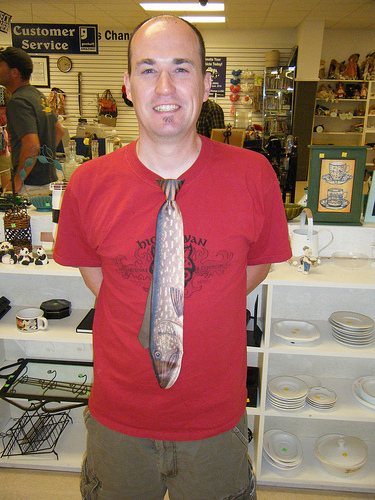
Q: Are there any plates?
A: Yes, there is a plate.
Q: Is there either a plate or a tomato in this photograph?
A: Yes, there is a plate.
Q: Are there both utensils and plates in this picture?
A: No, there is a plate but no utensils.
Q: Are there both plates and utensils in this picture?
A: No, there is a plate but no utensils.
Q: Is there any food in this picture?
A: No, there is no food.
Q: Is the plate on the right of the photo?
A: Yes, the plate is on the right of the image.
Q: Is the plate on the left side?
A: No, the plate is on the right of the image.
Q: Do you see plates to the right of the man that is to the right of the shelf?
A: Yes, there is a plate to the right of the man.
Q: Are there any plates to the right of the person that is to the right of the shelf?
A: Yes, there is a plate to the right of the man.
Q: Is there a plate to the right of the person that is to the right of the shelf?
A: Yes, there is a plate to the right of the man.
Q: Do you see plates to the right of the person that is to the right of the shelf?
A: Yes, there is a plate to the right of the man.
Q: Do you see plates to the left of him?
A: No, the plate is to the right of the man.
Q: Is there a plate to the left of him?
A: No, the plate is to the right of the man.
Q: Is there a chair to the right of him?
A: No, there is a plate to the right of the man.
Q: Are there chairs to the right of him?
A: No, there is a plate to the right of the man.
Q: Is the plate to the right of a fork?
A: No, the plate is to the right of a man.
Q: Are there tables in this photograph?
A: No, there are no tables.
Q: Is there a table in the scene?
A: No, there are no tables.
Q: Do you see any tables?
A: No, there are no tables.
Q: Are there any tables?
A: No, there are no tables.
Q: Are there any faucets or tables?
A: No, there are no tables or faucets.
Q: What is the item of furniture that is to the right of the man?
A: The piece of furniture is a shelf.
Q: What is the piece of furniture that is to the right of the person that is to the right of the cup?
A: The piece of furniture is a shelf.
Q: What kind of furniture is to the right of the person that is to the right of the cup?
A: The piece of furniture is a shelf.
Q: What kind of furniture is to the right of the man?
A: The piece of furniture is a shelf.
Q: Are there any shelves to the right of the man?
A: Yes, there is a shelf to the right of the man.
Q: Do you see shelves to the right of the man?
A: Yes, there is a shelf to the right of the man.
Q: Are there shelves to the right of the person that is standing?
A: Yes, there is a shelf to the right of the man.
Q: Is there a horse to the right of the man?
A: No, there is a shelf to the right of the man.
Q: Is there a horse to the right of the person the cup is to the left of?
A: No, there is a shelf to the right of the man.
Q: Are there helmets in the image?
A: No, there are no helmets.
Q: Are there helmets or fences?
A: No, there are no helmets or fences.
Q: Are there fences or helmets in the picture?
A: No, there are no helmets or fences.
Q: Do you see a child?
A: No, there are no children.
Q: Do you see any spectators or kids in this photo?
A: No, there are no kids or spectators.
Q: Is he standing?
A: Yes, the man is standing.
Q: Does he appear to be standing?
A: Yes, the man is standing.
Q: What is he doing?
A: The man is standing.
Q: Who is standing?
A: The man is standing.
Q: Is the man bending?
A: No, the man is standing.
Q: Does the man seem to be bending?
A: No, the man is standing.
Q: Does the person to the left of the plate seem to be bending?
A: No, the man is standing.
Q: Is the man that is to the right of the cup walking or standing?
A: The man is standing.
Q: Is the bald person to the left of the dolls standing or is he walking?
A: The man is standing.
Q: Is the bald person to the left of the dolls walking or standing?
A: The man is standing.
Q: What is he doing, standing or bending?
A: The man is standing.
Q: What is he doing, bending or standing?
A: The man is standing.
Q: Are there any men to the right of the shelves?
A: No, the man is to the left of the shelves.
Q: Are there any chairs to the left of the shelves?
A: No, there is a man to the left of the shelves.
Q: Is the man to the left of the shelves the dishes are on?
A: Yes, the man is to the left of the shelves.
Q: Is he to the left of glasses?
A: No, the man is to the left of the shelves.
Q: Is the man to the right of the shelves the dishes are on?
A: No, the man is to the left of the shelves.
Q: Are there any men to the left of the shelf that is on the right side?
A: Yes, there is a man to the left of the shelf.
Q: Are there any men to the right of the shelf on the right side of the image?
A: No, the man is to the left of the shelf.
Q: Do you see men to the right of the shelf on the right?
A: No, the man is to the left of the shelf.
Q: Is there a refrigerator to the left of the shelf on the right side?
A: No, there is a man to the left of the shelf.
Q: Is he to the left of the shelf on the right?
A: Yes, the man is to the left of the shelf.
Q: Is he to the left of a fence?
A: No, the man is to the left of the shelf.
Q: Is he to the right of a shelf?
A: No, the man is to the left of a shelf.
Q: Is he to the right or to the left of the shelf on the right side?
A: The man is to the left of the shelf.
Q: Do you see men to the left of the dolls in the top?
A: Yes, there is a man to the left of the dolls.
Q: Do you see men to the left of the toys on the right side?
A: Yes, there is a man to the left of the dolls.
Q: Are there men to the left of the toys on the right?
A: Yes, there is a man to the left of the dolls.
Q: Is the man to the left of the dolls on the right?
A: Yes, the man is to the left of the dolls.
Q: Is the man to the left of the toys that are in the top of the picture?
A: Yes, the man is to the left of the dolls.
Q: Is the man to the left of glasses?
A: No, the man is to the left of the dolls.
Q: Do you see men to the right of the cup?
A: Yes, there is a man to the right of the cup.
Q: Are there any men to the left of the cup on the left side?
A: No, the man is to the right of the cup.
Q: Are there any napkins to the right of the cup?
A: No, there is a man to the right of the cup.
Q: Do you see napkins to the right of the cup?
A: No, there is a man to the right of the cup.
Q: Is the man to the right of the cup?
A: Yes, the man is to the right of the cup.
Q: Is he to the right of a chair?
A: No, the man is to the right of the cup.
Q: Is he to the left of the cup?
A: No, the man is to the right of the cup.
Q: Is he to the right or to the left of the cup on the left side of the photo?
A: The man is to the right of the cup.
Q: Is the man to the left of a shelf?
A: No, the man is to the right of a shelf.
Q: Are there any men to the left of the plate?
A: Yes, there is a man to the left of the plate.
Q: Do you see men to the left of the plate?
A: Yes, there is a man to the left of the plate.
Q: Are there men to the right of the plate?
A: No, the man is to the left of the plate.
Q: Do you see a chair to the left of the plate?
A: No, there is a man to the left of the plate.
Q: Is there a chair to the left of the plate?
A: No, there is a man to the left of the plate.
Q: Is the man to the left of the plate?
A: Yes, the man is to the left of the plate.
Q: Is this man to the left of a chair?
A: No, the man is to the left of the plate.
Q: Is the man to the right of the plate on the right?
A: No, the man is to the left of the plate.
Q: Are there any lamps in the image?
A: No, there are no lamps.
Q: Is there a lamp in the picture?
A: No, there are no lamps.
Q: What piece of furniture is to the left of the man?
A: The piece of furniture is a shelf.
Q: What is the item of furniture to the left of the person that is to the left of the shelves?
A: The piece of furniture is a shelf.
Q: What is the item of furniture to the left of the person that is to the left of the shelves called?
A: The piece of furniture is a shelf.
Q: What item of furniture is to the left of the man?
A: The piece of furniture is a shelf.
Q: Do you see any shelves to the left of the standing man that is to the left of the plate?
A: Yes, there is a shelf to the left of the man.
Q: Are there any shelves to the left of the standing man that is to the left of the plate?
A: Yes, there is a shelf to the left of the man.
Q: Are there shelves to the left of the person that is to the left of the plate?
A: Yes, there is a shelf to the left of the man.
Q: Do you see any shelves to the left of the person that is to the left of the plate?
A: Yes, there is a shelf to the left of the man.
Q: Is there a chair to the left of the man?
A: No, there is a shelf to the left of the man.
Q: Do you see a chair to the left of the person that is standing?
A: No, there is a shelf to the left of the man.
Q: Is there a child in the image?
A: No, there are no children.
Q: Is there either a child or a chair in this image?
A: No, there are no children or chairs.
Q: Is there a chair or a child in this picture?
A: No, there are no children or chairs.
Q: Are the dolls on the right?
A: Yes, the dolls are on the right of the image.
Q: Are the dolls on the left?
A: No, the dolls are on the right of the image.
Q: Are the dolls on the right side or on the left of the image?
A: The dolls are on the right of the image.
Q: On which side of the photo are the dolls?
A: The dolls are on the right of the image.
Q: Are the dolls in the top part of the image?
A: Yes, the dolls are in the top of the image.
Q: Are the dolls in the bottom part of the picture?
A: No, the dolls are in the top of the image.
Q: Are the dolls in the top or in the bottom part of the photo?
A: The dolls are in the top of the image.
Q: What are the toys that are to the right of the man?
A: The toys are dolls.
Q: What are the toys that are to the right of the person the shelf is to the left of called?
A: The toys are dolls.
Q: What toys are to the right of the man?
A: The toys are dolls.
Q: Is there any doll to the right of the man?
A: Yes, there are dolls to the right of the man.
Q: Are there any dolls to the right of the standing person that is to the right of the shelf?
A: Yes, there are dolls to the right of the man.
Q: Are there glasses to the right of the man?
A: No, there are dolls to the right of the man.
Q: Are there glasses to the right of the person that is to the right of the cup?
A: No, there are dolls to the right of the man.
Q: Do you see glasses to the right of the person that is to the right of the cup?
A: No, there are dolls to the right of the man.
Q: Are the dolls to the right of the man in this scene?
A: Yes, the dolls are to the right of the man.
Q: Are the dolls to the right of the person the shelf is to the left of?
A: Yes, the dolls are to the right of the man.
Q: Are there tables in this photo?
A: No, there are no tables.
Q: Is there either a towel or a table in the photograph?
A: No, there are no tables or towels.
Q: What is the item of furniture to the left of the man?
A: The piece of furniture is a shelf.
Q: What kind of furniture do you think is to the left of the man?
A: The piece of furniture is a shelf.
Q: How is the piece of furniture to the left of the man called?
A: The piece of furniture is a shelf.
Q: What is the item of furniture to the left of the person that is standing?
A: The piece of furniture is a shelf.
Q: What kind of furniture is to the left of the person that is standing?
A: The piece of furniture is a shelf.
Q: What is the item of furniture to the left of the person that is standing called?
A: The piece of furniture is a shelf.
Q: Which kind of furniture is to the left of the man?
A: The piece of furniture is a shelf.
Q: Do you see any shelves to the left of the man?
A: Yes, there is a shelf to the left of the man.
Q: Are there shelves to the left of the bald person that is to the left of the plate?
A: Yes, there is a shelf to the left of the man.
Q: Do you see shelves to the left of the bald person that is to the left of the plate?
A: Yes, there is a shelf to the left of the man.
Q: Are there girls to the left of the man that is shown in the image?
A: No, there is a shelf to the left of the man.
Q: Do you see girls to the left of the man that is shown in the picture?
A: No, there is a shelf to the left of the man.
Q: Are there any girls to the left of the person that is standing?
A: No, there is a shelf to the left of the man.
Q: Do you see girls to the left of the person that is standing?
A: No, there is a shelf to the left of the man.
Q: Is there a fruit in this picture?
A: No, there are no fruits.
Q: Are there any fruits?
A: No, there are no fruits.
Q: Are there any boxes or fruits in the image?
A: No, there are no fruits or boxes.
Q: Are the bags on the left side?
A: Yes, the bags are on the left of the image.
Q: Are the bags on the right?
A: No, the bags are on the left of the image.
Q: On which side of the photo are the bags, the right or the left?
A: The bags are on the left of the image.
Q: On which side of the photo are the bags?
A: The bags are on the left of the image.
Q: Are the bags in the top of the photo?
A: Yes, the bags are in the top of the image.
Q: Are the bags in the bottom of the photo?
A: No, the bags are in the top of the image.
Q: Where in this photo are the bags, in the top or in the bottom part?
A: The bags are in the top of the image.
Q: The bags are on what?
A: The bags are on the wall.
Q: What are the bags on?
A: The bags are on the wall.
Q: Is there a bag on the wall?
A: Yes, there are bags on the wall.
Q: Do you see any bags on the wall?
A: Yes, there are bags on the wall.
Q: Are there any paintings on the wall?
A: No, there are bags on the wall.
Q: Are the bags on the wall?
A: Yes, the bags are on the wall.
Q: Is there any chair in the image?
A: No, there are no chairs.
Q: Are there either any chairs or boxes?
A: No, there are no chairs or boxes.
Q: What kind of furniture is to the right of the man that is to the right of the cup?
A: The pieces of furniture are shelves.